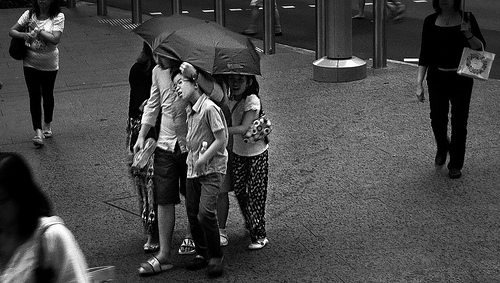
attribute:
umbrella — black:
[135, 14, 267, 83]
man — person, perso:
[149, 50, 192, 279]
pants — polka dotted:
[224, 146, 286, 251]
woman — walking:
[14, 64, 70, 149]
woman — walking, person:
[412, 0, 499, 180]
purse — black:
[7, 28, 30, 61]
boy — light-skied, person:
[171, 70, 239, 281]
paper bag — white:
[456, 42, 498, 80]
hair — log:
[26, 0, 71, 17]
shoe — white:
[27, 124, 60, 153]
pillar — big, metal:
[301, 0, 373, 85]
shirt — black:
[415, 14, 487, 79]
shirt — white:
[17, 15, 67, 79]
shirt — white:
[226, 99, 272, 157]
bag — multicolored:
[237, 116, 270, 146]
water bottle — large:
[133, 128, 158, 172]